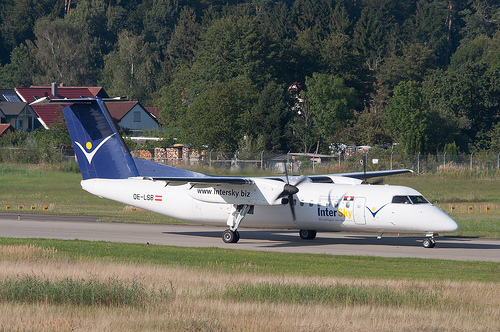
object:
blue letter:
[213, 187, 219, 195]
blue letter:
[207, 189, 212, 195]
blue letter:
[217, 187, 224, 196]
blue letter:
[246, 192, 251, 197]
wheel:
[221, 230, 241, 242]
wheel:
[298, 228, 317, 240]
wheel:
[422, 239, 435, 248]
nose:
[434, 209, 462, 235]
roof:
[28, 95, 139, 131]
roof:
[13, 86, 94, 102]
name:
[313, 205, 353, 220]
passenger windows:
[316, 198, 322, 206]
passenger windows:
[309, 199, 314, 207]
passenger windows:
[299, 199, 304, 206]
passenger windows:
[292, 199, 296, 206]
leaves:
[173, 0, 495, 131]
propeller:
[275, 160, 307, 221]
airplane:
[28, 83, 460, 248]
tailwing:
[29, 92, 134, 109]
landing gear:
[217, 211, 248, 245]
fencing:
[73, 150, 499, 174]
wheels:
[299, 227, 317, 240]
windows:
[391, 195, 411, 203]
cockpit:
[366, 179, 461, 234]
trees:
[419, 52, 500, 156]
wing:
[130, 166, 255, 186]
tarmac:
[0, 214, 499, 261]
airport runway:
[3, 208, 498, 261]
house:
[101, 97, 170, 135]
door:
[351, 196, 367, 224]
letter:
[320, 209, 325, 218]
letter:
[315, 205, 322, 217]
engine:
[185, 177, 301, 207]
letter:
[197, 186, 201, 195]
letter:
[200, 187, 208, 197]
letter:
[239, 189, 243, 198]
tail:
[26, 90, 144, 176]